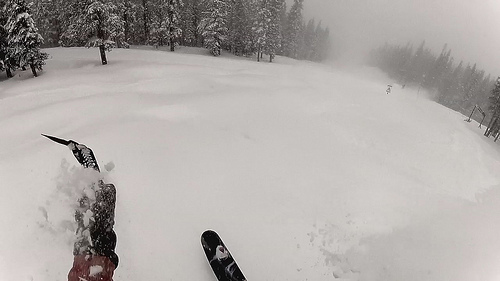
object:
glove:
[72, 179, 119, 266]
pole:
[39, 133, 68, 145]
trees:
[482, 76, 499, 137]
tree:
[156, 2, 185, 51]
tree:
[194, 0, 232, 56]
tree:
[247, 0, 283, 62]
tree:
[4, 5, 50, 77]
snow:
[0, 44, 499, 281]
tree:
[83, 1, 125, 66]